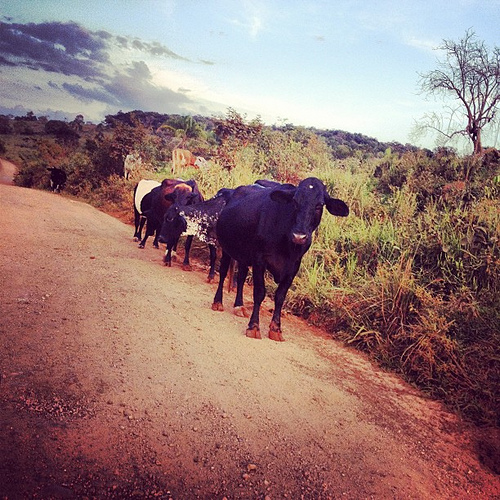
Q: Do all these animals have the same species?
A: Yes, all the animals are cows.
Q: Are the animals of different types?
A: No, all the animals are cows.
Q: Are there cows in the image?
A: Yes, there is a cow.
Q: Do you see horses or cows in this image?
A: Yes, there is a cow.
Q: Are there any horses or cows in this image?
A: Yes, there is a cow.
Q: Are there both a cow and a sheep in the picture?
A: No, there is a cow but no sheep.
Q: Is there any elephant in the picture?
A: No, there are no elephants.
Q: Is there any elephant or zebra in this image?
A: No, there are no elephants or zebras.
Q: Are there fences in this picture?
A: No, there are no fences.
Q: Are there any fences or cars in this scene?
A: No, there are no fences or cars.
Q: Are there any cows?
A: Yes, there is a cow.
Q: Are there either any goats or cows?
A: Yes, there is a cow.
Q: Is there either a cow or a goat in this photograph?
A: Yes, there is a cow.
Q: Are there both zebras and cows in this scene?
A: No, there is a cow but no zebras.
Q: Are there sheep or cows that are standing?
A: Yes, the cow is standing.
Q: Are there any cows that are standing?
A: Yes, there is a cow that is standing.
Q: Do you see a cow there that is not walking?
A: Yes, there is a cow that is standing .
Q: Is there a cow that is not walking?
A: Yes, there is a cow that is standing.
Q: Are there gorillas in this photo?
A: No, there are no gorillas.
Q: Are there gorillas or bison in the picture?
A: No, there are no gorillas or bison.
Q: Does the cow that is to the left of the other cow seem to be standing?
A: Yes, the cow is standing.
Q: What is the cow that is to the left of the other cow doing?
A: The cow is standing.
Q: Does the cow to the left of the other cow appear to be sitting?
A: No, the cow is standing.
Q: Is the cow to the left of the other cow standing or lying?
A: The cow is standing.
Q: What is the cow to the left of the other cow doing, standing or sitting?
A: The cow is standing.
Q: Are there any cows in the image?
A: Yes, there is a cow.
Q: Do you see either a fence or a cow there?
A: Yes, there is a cow.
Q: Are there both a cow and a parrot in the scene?
A: No, there is a cow but no parrots.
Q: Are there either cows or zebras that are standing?
A: Yes, the cow is standing.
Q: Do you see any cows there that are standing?
A: Yes, there is a cow that is standing.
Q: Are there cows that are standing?
A: Yes, there is a cow that is standing.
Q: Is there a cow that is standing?
A: Yes, there is a cow that is standing.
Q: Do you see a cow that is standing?
A: Yes, there is a cow that is standing.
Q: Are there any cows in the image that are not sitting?
A: Yes, there is a cow that is standing.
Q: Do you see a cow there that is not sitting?
A: Yes, there is a cow that is standing .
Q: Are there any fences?
A: No, there are no fences.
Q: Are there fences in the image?
A: No, there are no fences.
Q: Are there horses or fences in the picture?
A: No, there are no fences or horses.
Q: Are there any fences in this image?
A: No, there are no fences.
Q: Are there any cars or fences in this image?
A: No, there are no fences or cars.